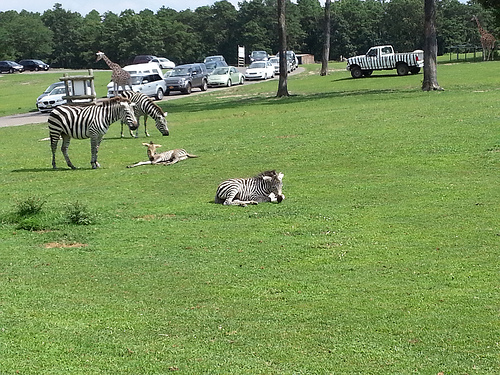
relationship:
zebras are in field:
[22, 88, 289, 210] [1, 69, 497, 372]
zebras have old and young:
[22, 88, 289, 210] [36, 85, 294, 219]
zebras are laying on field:
[22, 88, 289, 210] [1, 69, 497, 372]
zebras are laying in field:
[22, 88, 289, 210] [1, 69, 497, 372]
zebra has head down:
[120, 96, 177, 137] [153, 108, 174, 137]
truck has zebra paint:
[345, 46, 428, 79] [370, 60, 393, 68]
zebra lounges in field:
[120, 96, 177, 137] [1, 69, 497, 372]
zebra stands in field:
[120, 96, 177, 137] [1, 69, 497, 372]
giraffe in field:
[94, 50, 135, 94] [1, 69, 497, 372]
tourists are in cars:
[40, 41, 305, 116] [38, 44, 302, 119]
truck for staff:
[345, 46, 428, 79] [367, 46, 380, 62]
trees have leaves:
[4, 8, 499, 73] [117, 12, 149, 46]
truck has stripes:
[345, 46, 428, 79] [363, 53, 385, 72]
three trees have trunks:
[268, 0, 440, 99] [272, 68, 441, 97]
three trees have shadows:
[268, 0, 440, 99] [133, 83, 408, 119]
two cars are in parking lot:
[1, 54, 55, 73] [2, 65, 111, 76]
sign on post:
[237, 46, 248, 60] [236, 54, 250, 70]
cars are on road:
[38, 44, 302, 119] [7, 104, 53, 135]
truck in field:
[345, 46, 428, 79] [1, 69, 497, 372]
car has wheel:
[160, 61, 213, 100] [183, 79, 196, 90]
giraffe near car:
[94, 50, 135, 94] [160, 61, 213, 100]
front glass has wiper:
[208, 66, 232, 76] [220, 62, 229, 78]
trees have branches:
[4, 8, 499, 73] [51, 42, 81, 62]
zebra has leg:
[120, 96, 177, 137] [141, 109, 152, 141]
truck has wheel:
[345, 46, 428, 79] [349, 65, 368, 78]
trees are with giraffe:
[4, 8, 499, 73] [94, 50, 135, 94]